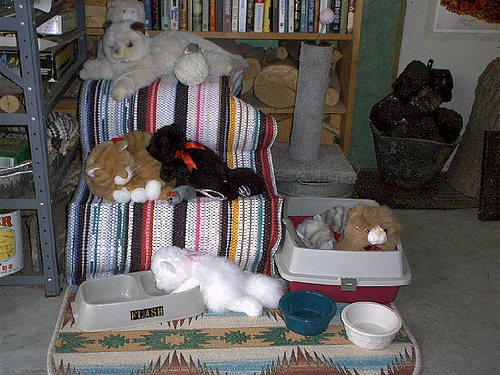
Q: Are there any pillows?
A: No, there are no pillows.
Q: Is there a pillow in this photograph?
A: No, there are no pillows.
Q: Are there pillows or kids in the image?
A: No, there are no pillows or kids.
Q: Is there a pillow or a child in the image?
A: No, there are no pillows or children.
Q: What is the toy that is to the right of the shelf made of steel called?
A: The toy is a stuffed animal.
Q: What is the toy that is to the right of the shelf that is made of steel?
A: The toy is a stuffed animal.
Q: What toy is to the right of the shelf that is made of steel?
A: The toy is a stuffed animal.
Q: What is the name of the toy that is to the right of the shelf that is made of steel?
A: The toy is a stuffed animal.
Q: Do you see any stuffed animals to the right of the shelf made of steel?
A: Yes, there is a stuffed animal to the right of the shelf.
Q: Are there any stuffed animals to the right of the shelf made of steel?
A: Yes, there is a stuffed animal to the right of the shelf.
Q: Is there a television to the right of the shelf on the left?
A: No, there is a stuffed animal to the right of the shelf.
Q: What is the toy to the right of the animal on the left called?
A: The toy is a stuffed animal.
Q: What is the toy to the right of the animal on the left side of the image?
A: The toy is a stuffed animal.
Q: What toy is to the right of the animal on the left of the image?
A: The toy is a stuffed animal.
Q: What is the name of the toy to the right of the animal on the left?
A: The toy is a stuffed animal.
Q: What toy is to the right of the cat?
A: The toy is a stuffed animal.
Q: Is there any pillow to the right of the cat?
A: No, there is a stuffed animal to the right of the cat.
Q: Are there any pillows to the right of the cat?
A: No, there is a stuffed animal to the right of the cat.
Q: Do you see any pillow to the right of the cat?
A: No, there is a stuffed animal to the right of the cat.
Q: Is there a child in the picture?
A: No, there are no children.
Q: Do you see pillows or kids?
A: No, there are no kids or pillows.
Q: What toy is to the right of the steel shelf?
A: The toy is a stuffed animal.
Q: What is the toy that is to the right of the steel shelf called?
A: The toy is a stuffed animal.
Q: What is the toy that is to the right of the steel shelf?
A: The toy is a stuffed animal.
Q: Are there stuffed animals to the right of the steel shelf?
A: Yes, there is a stuffed animal to the right of the shelf.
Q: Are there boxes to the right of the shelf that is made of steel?
A: No, there is a stuffed animal to the right of the shelf.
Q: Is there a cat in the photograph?
A: Yes, there is a cat.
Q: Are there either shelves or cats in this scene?
A: Yes, there is a cat.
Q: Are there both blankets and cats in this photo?
A: Yes, there are both a cat and a blanket.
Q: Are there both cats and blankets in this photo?
A: Yes, there are both a cat and a blanket.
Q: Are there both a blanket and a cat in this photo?
A: Yes, there are both a cat and a blanket.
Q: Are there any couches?
A: No, there are no couches.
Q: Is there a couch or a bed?
A: No, there are no couches or beds.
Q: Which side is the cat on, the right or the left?
A: The cat is on the left of the image.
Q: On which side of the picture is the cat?
A: The cat is on the left of the image.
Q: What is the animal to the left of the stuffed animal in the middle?
A: The animal is a cat.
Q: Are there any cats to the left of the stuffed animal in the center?
A: Yes, there is a cat to the left of the stuffed animal.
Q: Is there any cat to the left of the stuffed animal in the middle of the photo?
A: Yes, there is a cat to the left of the stuffed animal.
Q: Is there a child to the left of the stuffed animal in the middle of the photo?
A: No, there is a cat to the left of the stuffed animal.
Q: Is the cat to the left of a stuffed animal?
A: Yes, the cat is to the left of a stuffed animal.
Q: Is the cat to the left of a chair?
A: No, the cat is to the left of a stuffed animal.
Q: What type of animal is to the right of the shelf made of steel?
A: The animal is a cat.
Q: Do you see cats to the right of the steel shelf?
A: Yes, there is a cat to the right of the shelf.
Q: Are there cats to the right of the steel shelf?
A: Yes, there is a cat to the right of the shelf.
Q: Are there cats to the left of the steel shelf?
A: No, the cat is to the right of the shelf.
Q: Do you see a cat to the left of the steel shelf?
A: No, the cat is to the right of the shelf.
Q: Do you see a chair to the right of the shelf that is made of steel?
A: No, there is a cat to the right of the shelf.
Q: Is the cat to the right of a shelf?
A: Yes, the cat is to the right of a shelf.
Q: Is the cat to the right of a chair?
A: No, the cat is to the right of a shelf.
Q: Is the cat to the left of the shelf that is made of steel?
A: No, the cat is to the right of the shelf.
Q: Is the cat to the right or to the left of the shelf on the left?
A: The cat is to the right of the shelf.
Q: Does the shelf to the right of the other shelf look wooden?
A: Yes, the shelf is wooden.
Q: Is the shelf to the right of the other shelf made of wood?
A: Yes, the shelf is made of wood.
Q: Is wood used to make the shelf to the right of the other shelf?
A: Yes, the shelf is made of wood.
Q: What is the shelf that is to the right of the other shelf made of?
A: The shelf is made of wood.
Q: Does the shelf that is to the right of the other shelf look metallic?
A: No, the shelf is wooden.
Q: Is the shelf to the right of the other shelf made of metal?
A: No, the shelf is made of wood.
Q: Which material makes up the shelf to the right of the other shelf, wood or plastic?
A: The shelf is made of wood.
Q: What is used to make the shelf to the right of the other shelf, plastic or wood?
A: The shelf is made of wood.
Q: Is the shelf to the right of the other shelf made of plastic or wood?
A: The shelf is made of wood.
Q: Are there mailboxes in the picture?
A: No, there are no mailboxes.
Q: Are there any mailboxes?
A: No, there are no mailboxes.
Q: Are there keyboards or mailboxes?
A: No, there are no mailboxes or keyboards.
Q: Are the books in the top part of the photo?
A: Yes, the books are in the top of the image.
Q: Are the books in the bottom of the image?
A: No, the books are in the top of the image.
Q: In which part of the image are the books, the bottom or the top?
A: The books are in the top of the image.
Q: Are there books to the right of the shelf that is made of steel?
A: Yes, there are books to the right of the shelf.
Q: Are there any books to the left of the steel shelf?
A: No, the books are to the right of the shelf.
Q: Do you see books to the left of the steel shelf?
A: No, the books are to the right of the shelf.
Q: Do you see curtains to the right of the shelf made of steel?
A: No, there are books to the right of the shelf.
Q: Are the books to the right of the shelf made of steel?
A: Yes, the books are to the right of the shelf.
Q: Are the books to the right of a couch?
A: No, the books are to the right of the shelf.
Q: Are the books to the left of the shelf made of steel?
A: No, the books are to the right of the shelf.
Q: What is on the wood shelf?
A: The books are on the shelf.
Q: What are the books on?
A: The books are on the shelf.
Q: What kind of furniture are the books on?
A: The books are on the shelf.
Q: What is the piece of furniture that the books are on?
A: The piece of furniture is a shelf.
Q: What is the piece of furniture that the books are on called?
A: The piece of furniture is a shelf.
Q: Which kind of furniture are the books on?
A: The books are on the shelf.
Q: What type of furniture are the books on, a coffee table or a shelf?
A: The books are on a shelf.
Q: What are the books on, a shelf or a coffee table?
A: The books are on a shelf.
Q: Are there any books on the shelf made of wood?
A: Yes, there are books on the shelf.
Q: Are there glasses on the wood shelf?
A: No, there are books on the shelf.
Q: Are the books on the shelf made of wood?
A: Yes, the books are on the shelf.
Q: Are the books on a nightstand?
A: No, the books are on the shelf.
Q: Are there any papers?
A: No, there are no papers.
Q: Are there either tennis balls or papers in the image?
A: No, there are no papers or tennis balls.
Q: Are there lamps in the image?
A: No, there are no lamps.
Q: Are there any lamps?
A: No, there are no lamps.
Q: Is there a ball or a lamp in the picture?
A: No, there are no lamps or balls.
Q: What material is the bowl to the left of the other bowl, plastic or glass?
A: The bowl is made of plastic.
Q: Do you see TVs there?
A: No, there are no tvs.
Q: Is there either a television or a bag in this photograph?
A: No, there are no televisions or bags.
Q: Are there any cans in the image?
A: Yes, there is a can.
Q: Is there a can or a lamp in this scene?
A: Yes, there is a can.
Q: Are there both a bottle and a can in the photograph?
A: No, there is a can but no bottles.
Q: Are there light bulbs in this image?
A: No, there are no light bulbs.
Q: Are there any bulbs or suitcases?
A: No, there are no bulbs or suitcases.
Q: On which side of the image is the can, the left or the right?
A: The can is on the left of the image.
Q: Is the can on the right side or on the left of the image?
A: The can is on the left of the image.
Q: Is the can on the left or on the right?
A: The can is on the left of the image.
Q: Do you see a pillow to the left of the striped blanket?
A: No, there is a can to the left of the blanket.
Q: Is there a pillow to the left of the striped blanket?
A: No, there is a can to the left of the blanket.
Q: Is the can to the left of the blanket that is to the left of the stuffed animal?
A: Yes, the can is to the left of the blanket.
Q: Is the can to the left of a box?
A: No, the can is to the left of the blanket.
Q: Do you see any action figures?
A: No, there are no action figures.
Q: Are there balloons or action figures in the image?
A: No, there are no action figures or balloons.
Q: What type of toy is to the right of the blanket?
A: The toy is a stuffed animal.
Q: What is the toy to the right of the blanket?
A: The toy is a stuffed animal.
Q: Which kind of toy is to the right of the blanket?
A: The toy is a stuffed animal.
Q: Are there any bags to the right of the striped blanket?
A: No, there is a stuffed animal to the right of the blanket.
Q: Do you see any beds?
A: No, there are no beds.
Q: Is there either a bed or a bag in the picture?
A: No, there are no beds or bags.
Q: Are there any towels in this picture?
A: Yes, there is a towel.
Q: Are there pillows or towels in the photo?
A: Yes, there is a towel.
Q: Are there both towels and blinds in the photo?
A: No, there is a towel but no blinds.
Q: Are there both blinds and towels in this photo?
A: No, there is a towel but no blinds.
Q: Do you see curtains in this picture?
A: No, there are no curtains.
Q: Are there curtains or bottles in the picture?
A: No, there are no curtains or bottles.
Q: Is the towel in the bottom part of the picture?
A: Yes, the towel is in the bottom of the image.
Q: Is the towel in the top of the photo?
A: No, the towel is in the bottom of the image.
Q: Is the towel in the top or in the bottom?
A: The towel is in the bottom of the image.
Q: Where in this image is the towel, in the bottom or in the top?
A: The towel is in the bottom of the image.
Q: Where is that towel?
A: The towel is on the floor.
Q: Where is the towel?
A: The towel is on the floor.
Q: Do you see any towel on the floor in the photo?
A: Yes, there is a towel on the floor.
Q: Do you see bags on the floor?
A: No, there is a towel on the floor.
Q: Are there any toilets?
A: No, there are no toilets.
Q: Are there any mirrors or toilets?
A: No, there are no toilets or mirrors.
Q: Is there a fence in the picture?
A: No, there are no fences.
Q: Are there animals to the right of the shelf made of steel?
A: Yes, there is an animal to the right of the shelf.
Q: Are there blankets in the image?
A: Yes, there is a blanket.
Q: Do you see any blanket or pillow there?
A: Yes, there is a blanket.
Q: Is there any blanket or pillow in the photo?
A: Yes, there is a blanket.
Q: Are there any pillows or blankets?
A: Yes, there is a blanket.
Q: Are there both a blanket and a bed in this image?
A: No, there is a blanket but no beds.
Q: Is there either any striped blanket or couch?
A: Yes, there is a striped blanket.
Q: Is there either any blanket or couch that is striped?
A: Yes, the blanket is striped.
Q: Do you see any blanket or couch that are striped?
A: Yes, the blanket is striped.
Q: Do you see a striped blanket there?
A: Yes, there is a striped blanket.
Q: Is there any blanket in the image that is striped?
A: Yes, there is a blanket that is striped.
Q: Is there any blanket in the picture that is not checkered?
A: Yes, there is a striped blanket.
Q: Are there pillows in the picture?
A: No, there are no pillows.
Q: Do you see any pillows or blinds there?
A: No, there are no pillows or blinds.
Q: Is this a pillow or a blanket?
A: This is a blanket.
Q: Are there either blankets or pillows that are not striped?
A: No, there is a blanket but it is striped.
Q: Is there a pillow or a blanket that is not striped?
A: No, there is a blanket but it is striped.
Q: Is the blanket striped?
A: Yes, the blanket is striped.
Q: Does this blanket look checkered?
A: No, the blanket is striped.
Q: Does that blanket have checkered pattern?
A: No, the blanket is striped.